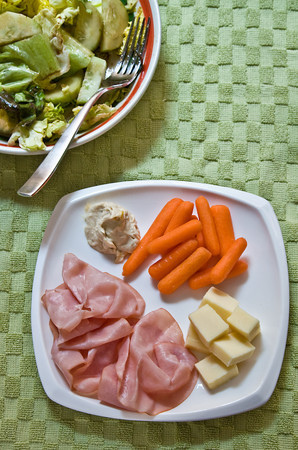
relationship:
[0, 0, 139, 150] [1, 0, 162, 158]
lettuce in bowl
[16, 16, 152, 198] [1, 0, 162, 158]
fork in bowl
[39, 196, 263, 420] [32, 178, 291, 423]
food on plate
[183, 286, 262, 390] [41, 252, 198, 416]
cheese near ham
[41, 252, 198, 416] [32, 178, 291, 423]
ham on plate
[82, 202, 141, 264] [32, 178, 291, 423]
dip on plate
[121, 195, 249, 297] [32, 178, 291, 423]
carrots on plate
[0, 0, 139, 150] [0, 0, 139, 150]
lettuce in lettuce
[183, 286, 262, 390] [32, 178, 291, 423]
cheese on plate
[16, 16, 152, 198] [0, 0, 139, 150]
fork in lettuce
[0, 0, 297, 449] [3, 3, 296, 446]
cloth on table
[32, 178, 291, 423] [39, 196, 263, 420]
plate has food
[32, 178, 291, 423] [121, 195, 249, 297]
plate has carrots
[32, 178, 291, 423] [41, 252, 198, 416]
plate has ham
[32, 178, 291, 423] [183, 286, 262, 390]
plate has cheese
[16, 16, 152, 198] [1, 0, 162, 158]
fork on side of bowl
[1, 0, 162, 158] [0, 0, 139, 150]
bowl has lettuce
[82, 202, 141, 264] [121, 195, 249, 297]
dip next to carrots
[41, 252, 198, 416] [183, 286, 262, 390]
ham next to cheese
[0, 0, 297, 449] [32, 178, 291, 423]
cloth under plate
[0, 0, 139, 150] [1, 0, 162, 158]
lettuce on bowl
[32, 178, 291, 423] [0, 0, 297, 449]
plate on cloth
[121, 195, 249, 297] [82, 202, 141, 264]
carrots with dip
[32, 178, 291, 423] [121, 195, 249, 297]
plate with carrots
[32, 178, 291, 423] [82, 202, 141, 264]
plate with dip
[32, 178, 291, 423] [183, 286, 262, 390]
plate with cheese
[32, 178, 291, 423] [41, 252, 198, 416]
plate with ham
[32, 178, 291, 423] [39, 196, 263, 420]
plate with food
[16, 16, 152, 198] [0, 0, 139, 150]
fork with lettuce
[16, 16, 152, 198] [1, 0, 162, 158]
fork with bowl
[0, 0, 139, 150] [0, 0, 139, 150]
lettuce with lettuce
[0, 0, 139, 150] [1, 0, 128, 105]
lettuce with cucumber